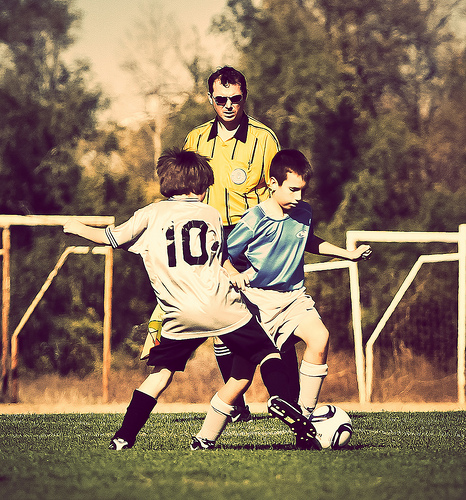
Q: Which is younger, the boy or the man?
A: The boy is younger than the man.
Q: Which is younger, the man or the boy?
A: The boy is younger than the man.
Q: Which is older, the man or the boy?
A: The man is older than the boy.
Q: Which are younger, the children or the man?
A: The children are younger than the man.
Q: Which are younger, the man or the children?
A: The children are younger than the man.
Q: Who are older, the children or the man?
A: The man are older than the children.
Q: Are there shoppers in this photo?
A: No, there are no shoppers.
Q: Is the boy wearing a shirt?
A: Yes, the boy is wearing a shirt.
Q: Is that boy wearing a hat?
A: No, the boy is wearing a shirt.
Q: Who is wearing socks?
A: The boy is wearing socks.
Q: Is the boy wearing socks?
A: Yes, the boy is wearing socks.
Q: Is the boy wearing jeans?
A: No, the boy is wearing socks.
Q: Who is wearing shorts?
A: The boy is wearing shorts.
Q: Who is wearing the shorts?
A: The boy is wearing shorts.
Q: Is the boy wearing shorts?
A: Yes, the boy is wearing shorts.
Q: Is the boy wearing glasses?
A: No, the boy is wearing shorts.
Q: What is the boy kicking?
A: The boy is kicking the ball.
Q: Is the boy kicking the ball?
A: Yes, the boy is kicking the ball.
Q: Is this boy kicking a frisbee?
A: No, the boy is kicking the ball.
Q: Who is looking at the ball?
A: The boy is looking at the ball.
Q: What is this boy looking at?
A: The boy is looking at the ball.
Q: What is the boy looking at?
A: The boy is looking at the ball.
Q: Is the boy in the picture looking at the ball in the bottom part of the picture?
A: Yes, the boy is looking at the ball.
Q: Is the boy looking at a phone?
A: No, the boy is looking at the ball.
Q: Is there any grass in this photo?
A: Yes, there is grass.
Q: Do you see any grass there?
A: Yes, there is grass.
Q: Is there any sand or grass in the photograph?
A: Yes, there is grass.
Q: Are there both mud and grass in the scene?
A: No, there is grass but no mud.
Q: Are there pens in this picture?
A: No, there are no pens.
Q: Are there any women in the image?
A: No, there are no women.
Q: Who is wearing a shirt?
A: The man is wearing a shirt.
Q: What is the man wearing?
A: The man is wearing a shirt.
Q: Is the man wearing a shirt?
A: Yes, the man is wearing a shirt.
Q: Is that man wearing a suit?
A: No, the man is wearing a shirt.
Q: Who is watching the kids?
A: The man is watching the kids.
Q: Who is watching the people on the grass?
A: The man is watching the kids.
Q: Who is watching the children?
A: The man is watching the kids.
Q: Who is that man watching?
A: The man is watching the children.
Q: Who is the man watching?
A: The man is watching the children.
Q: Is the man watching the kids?
A: Yes, the man is watching the kids.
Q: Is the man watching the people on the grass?
A: Yes, the man is watching the kids.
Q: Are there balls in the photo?
A: Yes, there is a ball.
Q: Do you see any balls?
A: Yes, there is a ball.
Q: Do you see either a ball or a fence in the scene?
A: Yes, there is a ball.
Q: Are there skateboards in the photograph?
A: No, there are no skateboards.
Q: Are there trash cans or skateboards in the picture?
A: No, there are no skateboards or trash cans.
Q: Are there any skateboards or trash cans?
A: No, there are no skateboards or trash cans.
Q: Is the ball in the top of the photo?
A: No, the ball is in the bottom of the image.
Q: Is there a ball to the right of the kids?
A: Yes, there is a ball to the right of the kids.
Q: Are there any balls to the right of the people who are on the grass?
A: Yes, there is a ball to the right of the kids.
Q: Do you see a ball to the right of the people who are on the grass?
A: Yes, there is a ball to the right of the kids.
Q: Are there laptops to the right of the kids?
A: No, there is a ball to the right of the kids.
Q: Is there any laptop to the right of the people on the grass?
A: No, there is a ball to the right of the kids.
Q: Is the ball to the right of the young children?
A: Yes, the ball is to the right of the kids.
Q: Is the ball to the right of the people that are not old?
A: Yes, the ball is to the right of the kids.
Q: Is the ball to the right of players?
A: No, the ball is to the right of the kids.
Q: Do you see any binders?
A: No, there are no binders.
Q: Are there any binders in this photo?
A: No, there are no binders.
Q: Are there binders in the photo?
A: No, there are no binders.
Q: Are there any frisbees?
A: No, there are no frisbees.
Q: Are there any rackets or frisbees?
A: No, there are no frisbees or rackets.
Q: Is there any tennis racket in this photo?
A: No, there are no rackets.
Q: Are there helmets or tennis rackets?
A: No, there are no tennis rackets or helmets.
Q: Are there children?
A: Yes, there are children.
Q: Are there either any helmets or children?
A: Yes, there are children.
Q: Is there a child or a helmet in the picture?
A: Yes, there are children.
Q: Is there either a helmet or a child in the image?
A: Yes, there are children.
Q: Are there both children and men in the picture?
A: Yes, there are both children and a man.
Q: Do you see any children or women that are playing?
A: Yes, the children are playing.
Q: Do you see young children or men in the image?
A: Yes, there are young children.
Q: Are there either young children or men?
A: Yes, there are young children.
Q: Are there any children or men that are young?
A: Yes, the children are young.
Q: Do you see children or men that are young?
A: Yes, the children are young.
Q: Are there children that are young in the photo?
A: Yes, there are young children.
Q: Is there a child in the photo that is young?
A: Yes, there are children that are young.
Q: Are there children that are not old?
A: Yes, there are young children.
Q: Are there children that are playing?
A: Yes, there are children that are playing.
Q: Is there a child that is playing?
A: Yes, there are children that are playing.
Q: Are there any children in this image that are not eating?
A: Yes, there are children that are playing.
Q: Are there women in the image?
A: No, there are no women.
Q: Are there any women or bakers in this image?
A: No, there are no women or bakers.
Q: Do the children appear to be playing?
A: Yes, the children are playing.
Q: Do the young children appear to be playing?
A: Yes, the children are playing.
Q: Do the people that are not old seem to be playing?
A: Yes, the children are playing.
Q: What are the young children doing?
A: The children are playing.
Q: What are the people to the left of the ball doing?
A: The children are playing.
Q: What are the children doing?
A: The children are playing.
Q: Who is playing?
A: The children are playing.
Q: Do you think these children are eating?
A: No, the children are playing.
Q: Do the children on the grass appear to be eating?
A: No, the kids are playing.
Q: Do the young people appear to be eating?
A: No, the kids are playing.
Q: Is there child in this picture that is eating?
A: No, there are children but they are playing.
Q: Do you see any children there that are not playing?
A: No, there are children but they are playing.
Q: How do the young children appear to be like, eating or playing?
A: The children are playing.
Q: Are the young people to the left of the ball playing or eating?
A: The children are playing.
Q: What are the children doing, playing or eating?
A: The children are playing.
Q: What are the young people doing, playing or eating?
A: The children are playing.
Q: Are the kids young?
A: Yes, the kids are young.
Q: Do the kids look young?
A: Yes, the kids are young.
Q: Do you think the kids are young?
A: Yes, the kids are young.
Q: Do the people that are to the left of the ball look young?
A: Yes, the kids are young.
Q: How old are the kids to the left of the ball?
A: The kids are young.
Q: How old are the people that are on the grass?
A: The kids are young.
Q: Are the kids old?
A: No, the kids are young.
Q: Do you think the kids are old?
A: No, the kids are young.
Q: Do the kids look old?
A: No, the kids are young.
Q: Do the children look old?
A: No, the children are young.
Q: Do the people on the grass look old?
A: No, the children are young.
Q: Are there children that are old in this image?
A: No, there are children but they are young.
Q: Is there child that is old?
A: No, there are children but they are young.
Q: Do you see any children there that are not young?
A: No, there are children but they are young.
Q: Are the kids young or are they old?
A: The kids are young.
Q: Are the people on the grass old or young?
A: The kids are young.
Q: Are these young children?
A: Yes, these are young children.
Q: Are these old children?
A: No, these are young children.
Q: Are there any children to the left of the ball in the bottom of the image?
A: Yes, there are children to the left of the ball.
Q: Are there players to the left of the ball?
A: No, there are children to the left of the ball.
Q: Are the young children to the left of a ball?
A: Yes, the kids are to the left of a ball.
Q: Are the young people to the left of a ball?
A: Yes, the kids are to the left of a ball.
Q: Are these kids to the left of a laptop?
A: No, the kids are to the left of a ball.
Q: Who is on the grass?
A: The kids are on the grass.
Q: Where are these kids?
A: The kids are on the grass.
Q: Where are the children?
A: The kids are on the grass.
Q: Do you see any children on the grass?
A: Yes, there are children on the grass.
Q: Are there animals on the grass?
A: No, there are children on the grass.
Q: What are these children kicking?
A: The children are kicking the ball.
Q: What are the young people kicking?
A: The children are kicking the ball.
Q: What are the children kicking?
A: The children are kicking the ball.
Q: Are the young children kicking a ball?
A: Yes, the kids are kicking a ball.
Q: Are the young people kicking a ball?
A: Yes, the kids are kicking a ball.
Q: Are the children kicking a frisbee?
A: No, the children are kicking a ball.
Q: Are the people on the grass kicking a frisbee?
A: No, the children are kicking a ball.